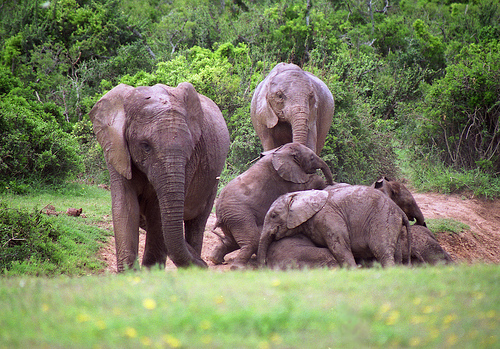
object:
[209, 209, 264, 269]
legs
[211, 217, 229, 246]
tail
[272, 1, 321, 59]
trees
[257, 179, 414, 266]
baby elephant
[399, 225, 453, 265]
baby elephant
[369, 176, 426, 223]
baby elephant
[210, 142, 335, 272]
baby elephant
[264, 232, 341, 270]
baby elephant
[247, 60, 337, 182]
elephant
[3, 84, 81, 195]
vegetation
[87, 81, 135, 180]
ear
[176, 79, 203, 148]
ear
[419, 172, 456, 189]
ground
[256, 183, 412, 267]
elephant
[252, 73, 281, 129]
ear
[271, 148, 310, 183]
ear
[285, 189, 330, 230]
ear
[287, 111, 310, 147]
trunk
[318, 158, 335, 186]
trunk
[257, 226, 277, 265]
trunk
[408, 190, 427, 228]
trunk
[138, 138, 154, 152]
eye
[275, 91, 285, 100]
eye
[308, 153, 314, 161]
eye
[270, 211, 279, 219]
eye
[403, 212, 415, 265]
tail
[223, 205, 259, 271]
leg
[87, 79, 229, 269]
elephants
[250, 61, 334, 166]
elephants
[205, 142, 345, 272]
elephants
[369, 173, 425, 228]
elephants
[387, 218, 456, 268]
elephants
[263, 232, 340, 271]
elephants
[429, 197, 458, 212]
ground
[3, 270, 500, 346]
grass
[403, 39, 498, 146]
tree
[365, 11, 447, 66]
tree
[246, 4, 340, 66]
tree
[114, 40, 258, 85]
tree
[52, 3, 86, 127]
tree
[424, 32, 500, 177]
trees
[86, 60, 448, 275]
elephants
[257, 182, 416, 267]
elephant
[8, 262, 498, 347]
grassy area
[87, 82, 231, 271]
elephant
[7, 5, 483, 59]
forest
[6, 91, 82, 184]
woods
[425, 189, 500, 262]
dirt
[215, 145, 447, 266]
elephants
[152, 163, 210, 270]
trunk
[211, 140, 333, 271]
elephant